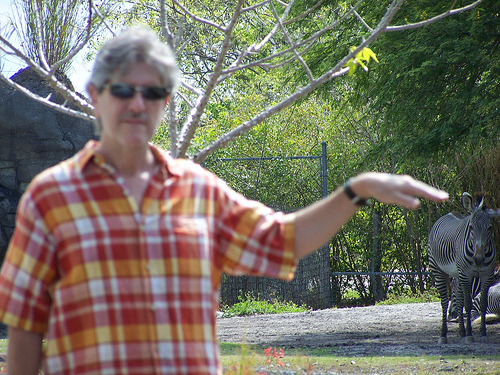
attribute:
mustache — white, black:
[119, 110, 148, 120]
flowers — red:
[262, 345, 283, 369]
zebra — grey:
[416, 194, 498, 344]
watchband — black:
[319, 183, 389, 218]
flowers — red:
[261, 340, 289, 371]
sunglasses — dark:
[104, 76, 174, 103]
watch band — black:
[342, 182, 365, 209]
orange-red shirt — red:
[1, 137, 293, 370]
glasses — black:
[101, 82, 172, 101]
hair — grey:
[88, 21, 182, 99]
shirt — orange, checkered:
[8, 137, 308, 373]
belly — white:
[437, 257, 458, 273]